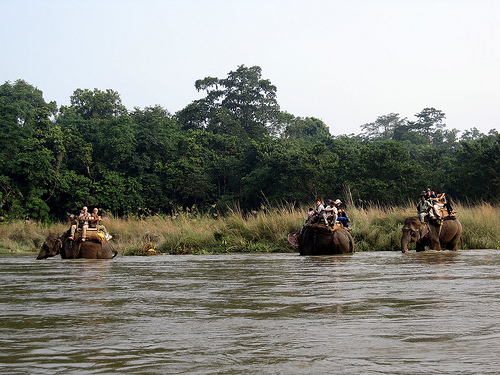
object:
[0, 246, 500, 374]
water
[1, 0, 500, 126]
sky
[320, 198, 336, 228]
people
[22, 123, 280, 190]
leaves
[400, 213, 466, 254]
elephant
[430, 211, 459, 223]
seat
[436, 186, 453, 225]
people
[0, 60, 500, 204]
jungle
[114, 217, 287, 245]
grass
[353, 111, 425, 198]
trees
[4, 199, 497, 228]
land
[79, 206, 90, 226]
man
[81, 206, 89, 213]
hat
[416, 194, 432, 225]
man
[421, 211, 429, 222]
pants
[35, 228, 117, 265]
elephant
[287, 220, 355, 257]
elephant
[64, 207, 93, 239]
people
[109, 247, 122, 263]
tail